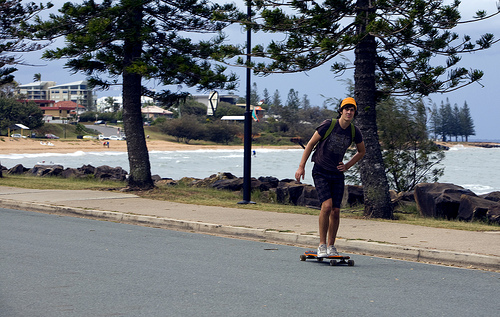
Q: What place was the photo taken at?
A: It was taken at the road.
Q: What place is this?
A: It is a road.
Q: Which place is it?
A: It is a road.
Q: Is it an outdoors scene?
A: Yes, it is outdoors.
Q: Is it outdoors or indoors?
A: It is outdoors.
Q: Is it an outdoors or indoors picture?
A: It is outdoors.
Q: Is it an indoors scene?
A: No, it is outdoors.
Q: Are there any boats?
A: No, there are no boats.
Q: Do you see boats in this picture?
A: No, there are no boats.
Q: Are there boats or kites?
A: No, there are no boats or kites.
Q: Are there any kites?
A: No, there are no kites.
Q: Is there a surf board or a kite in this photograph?
A: No, there are no kites or surfboards.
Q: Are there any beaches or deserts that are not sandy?
A: No, there is a beach but it is sandy.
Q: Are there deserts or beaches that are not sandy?
A: No, there is a beach but it is sandy.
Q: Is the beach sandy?
A: Yes, the beach is sandy.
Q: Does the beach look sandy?
A: Yes, the beach is sandy.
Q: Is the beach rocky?
A: No, the beach is sandy.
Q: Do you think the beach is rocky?
A: No, the beach is sandy.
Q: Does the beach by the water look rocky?
A: No, the beach is sandy.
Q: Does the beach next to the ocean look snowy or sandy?
A: The beach is sandy.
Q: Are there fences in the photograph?
A: No, there are no fences.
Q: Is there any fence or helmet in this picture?
A: No, there are no fences or helmets.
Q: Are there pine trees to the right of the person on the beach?
A: Yes, there is a pine tree to the right of the person.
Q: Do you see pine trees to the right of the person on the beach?
A: Yes, there is a pine tree to the right of the person.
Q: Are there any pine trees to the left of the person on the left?
A: No, the pine tree is to the right of the person.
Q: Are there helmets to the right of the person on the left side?
A: No, there is a pine tree to the right of the person.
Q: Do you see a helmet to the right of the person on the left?
A: No, there is a pine tree to the right of the person.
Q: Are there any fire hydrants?
A: No, there are no fire hydrants.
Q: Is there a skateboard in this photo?
A: Yes, there is a skateboard.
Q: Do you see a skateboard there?
A: Yes, there is a skateboard.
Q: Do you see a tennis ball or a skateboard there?
A: Yes, there is a skateboard.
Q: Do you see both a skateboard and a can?
A: No, there is a skateboard but no cans.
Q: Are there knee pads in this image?
A: No, there are no knee pads.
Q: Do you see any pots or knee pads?
A: No, there are no knee pads or pots.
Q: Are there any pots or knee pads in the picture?
A: No, there are no knee pads or pots.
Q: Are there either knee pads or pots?
A: No, there are no knee pads or pots.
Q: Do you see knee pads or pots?
A: No, there are no knee pads or pots.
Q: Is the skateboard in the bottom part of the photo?
A: Yes, the skateboard is in the bottom of the image.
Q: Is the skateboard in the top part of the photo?
A: No, the skateboard is in the bottom of the image.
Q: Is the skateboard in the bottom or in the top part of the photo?
A: The skateboard is in the bottom of the image.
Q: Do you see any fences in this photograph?
A: No, there are no fences.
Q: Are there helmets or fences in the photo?
A: No, there are no fences or helmets.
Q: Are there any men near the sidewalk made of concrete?
A: Yes, there is a man near the sidewalk.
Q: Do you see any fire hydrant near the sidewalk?
A: No, there is a man near the sidewalk.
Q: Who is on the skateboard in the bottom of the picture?
A: The man is on the skateboard.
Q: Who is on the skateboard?
A: The man is on the skateboard.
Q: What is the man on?
A: The man is on the skateboard.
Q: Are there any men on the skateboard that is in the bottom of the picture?
A: Yes, there is a man on the skateboard.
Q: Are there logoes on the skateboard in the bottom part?
A: No, there is a man on the skateboard.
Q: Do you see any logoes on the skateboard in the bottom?
A: No, there is a man on the skateboard.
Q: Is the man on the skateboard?
A: Yes, the man is on the skateboard.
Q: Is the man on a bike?
A: No, the man is on the skateboard.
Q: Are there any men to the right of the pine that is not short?
A: Yes, there is a man to the right of the pine.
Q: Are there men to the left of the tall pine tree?
A: No, the man is to the right of the pine.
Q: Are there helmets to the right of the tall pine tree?
A: No, there is a man to the right of the pine tree.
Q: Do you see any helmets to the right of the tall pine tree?
A: No, there is a man to the right of the pine tree.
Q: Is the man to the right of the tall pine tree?
A: Yes, the man is to the right of the pine tree.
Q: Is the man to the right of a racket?
A: No, the man is to the right of the pine tree.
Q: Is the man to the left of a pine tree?
A: No, the man is to the right of a pine tree.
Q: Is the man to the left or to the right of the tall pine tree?
A: The man is to the right of the pine tree.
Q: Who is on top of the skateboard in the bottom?
A: The man is on top of the skateboard.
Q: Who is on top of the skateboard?
A: The man is on top of the skateboard.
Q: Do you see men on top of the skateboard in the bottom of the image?
A: Yes, there is a man on top of the skateboard.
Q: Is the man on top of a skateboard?
A: Yes, the man is on top of a skateboard.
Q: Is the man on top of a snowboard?
A: No, the man is on top of a skateboard.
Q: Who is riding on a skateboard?
A: The man is riding on a skateboard.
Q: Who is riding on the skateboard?
A: The man is riding on a skateboard.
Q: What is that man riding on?
A: The man is riding on a skateboard.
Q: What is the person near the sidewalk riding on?
A: The man is riding on a skateboard.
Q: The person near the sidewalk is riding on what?
A: The man is riding on a skateboard.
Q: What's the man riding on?
A: The man is riding on a skateboard.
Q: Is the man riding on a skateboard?
A: Yes, the man is riding on a skateboard.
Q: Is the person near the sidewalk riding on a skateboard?
A: Yes, the man is riding on a skateboard.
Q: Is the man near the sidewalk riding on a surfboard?
A: No, the man is riding on a skateboard.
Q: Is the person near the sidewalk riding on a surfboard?
A: No, the man is riding on a skateboard.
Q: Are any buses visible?
A: No, there are no buses.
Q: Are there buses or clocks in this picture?
A: No, there are no buses or clocks.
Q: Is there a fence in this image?
A: No, there are no fences.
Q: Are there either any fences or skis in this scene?
A: No, there are no fences or skis.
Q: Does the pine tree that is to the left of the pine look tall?
A: Yes, the pine tree is tall.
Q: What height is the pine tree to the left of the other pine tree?
A: The pine is tall.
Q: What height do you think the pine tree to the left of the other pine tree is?
A: The pine is tall.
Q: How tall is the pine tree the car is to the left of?
A: The pine tree is tall.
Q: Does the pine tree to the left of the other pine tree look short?
A: No, the pine tree is tall.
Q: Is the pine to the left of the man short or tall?
A: The pine is tall.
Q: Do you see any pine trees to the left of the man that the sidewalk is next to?
A: Yes, there is a pine tree to the left of the man.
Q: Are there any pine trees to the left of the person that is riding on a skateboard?
A: Yes, there is a pine tree to the left of the man.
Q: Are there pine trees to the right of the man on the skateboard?
A: No, the pine tree is to the left of the man.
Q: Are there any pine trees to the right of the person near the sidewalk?
A: No, the pine tree is to the left of the man.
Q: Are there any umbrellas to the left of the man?
A: No, there is a pine tree to the left of the man.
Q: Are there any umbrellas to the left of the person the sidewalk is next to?
A: No, there is a pine tree to the left of the man.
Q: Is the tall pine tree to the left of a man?
A: Yes, the pine is to the left of a man.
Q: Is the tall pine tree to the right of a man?
A: No, the pine is to the left of a man.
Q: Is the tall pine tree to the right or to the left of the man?
A: The pine is to the left of the man.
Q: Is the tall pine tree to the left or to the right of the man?
A: The pine is to the left of the man.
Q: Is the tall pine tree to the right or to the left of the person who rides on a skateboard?
A: The pine is to the left of the man.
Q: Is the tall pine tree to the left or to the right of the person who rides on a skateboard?
A: The pine is to the left of the man.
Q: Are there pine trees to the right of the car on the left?
A: Yes, there is a pine tree to the right of the car.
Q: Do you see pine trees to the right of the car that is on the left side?
A: Yes, there is a pine tree to the right of the car.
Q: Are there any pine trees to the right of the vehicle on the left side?
A: Yes, there is a pine tree to the right of the car.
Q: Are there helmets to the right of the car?
A: No, there is a pine tree to the right of the car.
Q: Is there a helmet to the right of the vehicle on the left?
A: No, there is a pine tree to the right of the car.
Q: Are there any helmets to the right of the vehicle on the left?
A: No, there is a pine tree to the right of the car.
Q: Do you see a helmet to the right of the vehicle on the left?
A: No, there is a pine tree to the right of the car.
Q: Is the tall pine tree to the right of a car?
A: Yes, the pine is to the right of a car.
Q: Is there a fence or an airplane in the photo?
A: No, there are no fences or airplanes.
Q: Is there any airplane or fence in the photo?
A: No, there are no fences or airplanes.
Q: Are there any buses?
A: No, there are no buses.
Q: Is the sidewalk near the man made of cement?
A: Yes, the sidewalk is made of cement.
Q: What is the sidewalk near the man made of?
A: The sidewalk is made of cement.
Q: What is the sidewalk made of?
A: The sidewalk is made of concrete.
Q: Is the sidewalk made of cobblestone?
A: No, the sidewalk is made of concrete.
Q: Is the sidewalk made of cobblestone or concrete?
A: The sidewalk is made of concrete.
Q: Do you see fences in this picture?
A: No, there are no fences.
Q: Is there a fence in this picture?
A: No, there are no fences.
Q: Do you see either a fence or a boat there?
A: No, there are no fences or boats.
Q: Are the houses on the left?
A: Yes, the houses are on the left of the image.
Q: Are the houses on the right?
A: No, the houses are on the left of the image.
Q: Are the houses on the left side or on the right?
A: The houses are on the left of the image.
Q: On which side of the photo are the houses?
A: The houses are on the left of the image.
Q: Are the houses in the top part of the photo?
A: Yes, the houses are in the top of the image.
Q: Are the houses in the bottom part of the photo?
A: No, the houses are in the top of the image.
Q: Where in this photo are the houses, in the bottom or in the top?
A: The houses are in the top of the image.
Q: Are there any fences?
A: No, there are no fences.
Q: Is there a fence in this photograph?
A: No, there are no fences.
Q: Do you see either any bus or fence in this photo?
A: No, there are no fences or buses.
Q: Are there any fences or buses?
A: No, there are no fences or buses.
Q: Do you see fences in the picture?
A: No, there are no fences.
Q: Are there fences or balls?
A: No, there are no fences or balls.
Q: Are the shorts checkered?
A: Yes, the shorts are checkered.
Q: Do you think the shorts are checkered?
A: Yes, the shorts are checkered.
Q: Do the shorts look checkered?
A: Yes, the shorts are checkered.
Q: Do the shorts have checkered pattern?
A: Yes, the shorts are checkered.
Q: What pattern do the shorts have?
A: The shorts have checkered pattern.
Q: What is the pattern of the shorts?
A: The shorts are checkered.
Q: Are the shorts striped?
A: No, the shorts are checkered.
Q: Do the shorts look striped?
A: No, the shorts are checkered.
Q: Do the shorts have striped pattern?
A: No, the shorts are checkered.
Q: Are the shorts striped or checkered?
A: The shorts are checkered.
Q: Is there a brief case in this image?
A: No, there are no briefcases.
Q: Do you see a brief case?
A: No, there are no briefcases.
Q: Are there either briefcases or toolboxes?
A: No, there are no briefcases or toolboxes.